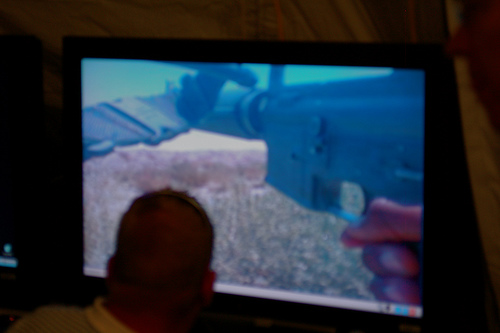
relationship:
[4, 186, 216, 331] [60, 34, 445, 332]
man watching tv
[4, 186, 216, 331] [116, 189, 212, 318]
man has hair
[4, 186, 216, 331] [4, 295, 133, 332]
man wearing shirt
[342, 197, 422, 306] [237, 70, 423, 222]
person holding gun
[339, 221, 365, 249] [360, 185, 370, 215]
finger under trigger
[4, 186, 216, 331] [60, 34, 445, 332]
man with tv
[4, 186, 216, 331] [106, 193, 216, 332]
man has head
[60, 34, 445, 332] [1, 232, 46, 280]
tv of computer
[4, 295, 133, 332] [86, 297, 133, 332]
shirt has collar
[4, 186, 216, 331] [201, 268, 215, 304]
man has ear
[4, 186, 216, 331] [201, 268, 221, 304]
man has ear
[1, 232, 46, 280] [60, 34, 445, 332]
computer has screen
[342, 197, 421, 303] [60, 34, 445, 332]
hand on screen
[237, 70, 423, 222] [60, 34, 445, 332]
gun on tv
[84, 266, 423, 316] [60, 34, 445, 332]
bar on tv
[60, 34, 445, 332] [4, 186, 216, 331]
tv in front of man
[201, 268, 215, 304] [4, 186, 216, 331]
ear on right of man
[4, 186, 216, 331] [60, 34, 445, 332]
man looking at tv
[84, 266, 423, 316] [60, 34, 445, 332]
bar at bottom of tv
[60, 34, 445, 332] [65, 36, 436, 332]
tv shaped rectangular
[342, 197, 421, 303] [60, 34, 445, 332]
hand on tv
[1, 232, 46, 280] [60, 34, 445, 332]
computer has tv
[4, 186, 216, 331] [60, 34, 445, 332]
man by tv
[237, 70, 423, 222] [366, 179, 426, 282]
gun has handle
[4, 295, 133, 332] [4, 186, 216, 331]
shirt on man